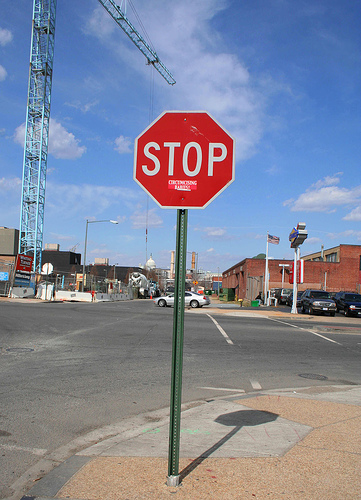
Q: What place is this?
A: It is a street.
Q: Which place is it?
A: It is a street.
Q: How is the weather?
A: It is clear.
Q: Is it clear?
A: Yes, it is clear.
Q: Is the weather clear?
A: Yes, it is clear.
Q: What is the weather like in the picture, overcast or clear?
A: It is clear.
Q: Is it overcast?
A: No, it is clear.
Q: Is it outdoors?
A: Yes, it is outdoors.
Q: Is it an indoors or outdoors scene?
A: It is outdoors.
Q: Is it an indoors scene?
A: No, it is outdoors.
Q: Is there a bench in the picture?
A: No, there are no benches.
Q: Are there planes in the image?
A: No, there are no planes.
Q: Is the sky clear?
A: Yes, the sky is clear.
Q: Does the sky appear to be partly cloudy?
A: No, the sky is clear.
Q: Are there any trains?
A: No, there are no trains.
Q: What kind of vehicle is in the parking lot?
A: The vehicles are cars.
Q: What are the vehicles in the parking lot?
A: The vehicles are cars.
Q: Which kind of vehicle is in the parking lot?
A: The vehicles are cars.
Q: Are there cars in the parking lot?
A: Yes, there are cars in the parking lot.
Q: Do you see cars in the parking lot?
A: Yes, there are cars in the parking lot.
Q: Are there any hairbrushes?
A: No, there are no hairbrushes.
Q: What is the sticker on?
A: The sticker is on the sign.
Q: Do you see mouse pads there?
A: No, there are no mouse pads.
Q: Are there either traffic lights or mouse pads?
A: No, there are no mouse pads or traffic lights.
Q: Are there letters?
A: Yes, there are letters.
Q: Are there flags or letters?
A: Yes, there are letters.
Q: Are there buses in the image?
A: No, there are no buses.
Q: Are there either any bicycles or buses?
A: No, there are no buses or bicycles.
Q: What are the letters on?
A: The letters are on the sign.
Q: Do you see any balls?
A: No, there are no balls.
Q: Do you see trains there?
A: No, there are no trains.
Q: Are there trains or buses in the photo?
A: No, there are no trains or buses.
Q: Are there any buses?
A: No, there are no buses.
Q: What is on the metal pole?
A: The sign is on the pole.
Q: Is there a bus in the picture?
A: No, there are no buses.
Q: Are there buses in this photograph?
A: No, there are no buses.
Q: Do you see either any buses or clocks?
A: No, there are no buses or clocks.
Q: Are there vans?
A: No, there are no vans.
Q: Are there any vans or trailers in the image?
A: No, there are no vans or trailers.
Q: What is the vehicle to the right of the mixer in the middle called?
A: The vehicle is a car.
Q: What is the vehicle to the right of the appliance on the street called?
A: The vehicle is a car.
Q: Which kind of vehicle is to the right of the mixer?
A: The vehicle is a car.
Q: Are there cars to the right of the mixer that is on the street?
A: Yes, there is a car to the right of the mixer.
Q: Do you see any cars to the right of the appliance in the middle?
A: Yes, there is a car to the right of the mixer.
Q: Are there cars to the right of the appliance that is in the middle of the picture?
A: Yes, there is a car to the right of the mixer.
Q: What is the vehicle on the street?
A: The vehicle is a car.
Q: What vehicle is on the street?
A: The vehicle is a car.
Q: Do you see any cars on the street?
A: Yes, there is a car on the street.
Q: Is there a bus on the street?
A: No, there is a car on the street.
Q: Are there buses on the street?
A: No, there is a car on the street.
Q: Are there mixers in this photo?
A: Yes, there is a mixer.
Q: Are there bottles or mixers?
A: Yes, there is a mixer.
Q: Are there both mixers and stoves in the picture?
A: No, there is a mixer but no stoves.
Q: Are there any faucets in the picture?
A: No, there are no faucets.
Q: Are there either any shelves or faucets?
A: No, there are no faucets or shelves.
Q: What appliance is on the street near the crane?
A: The appliance is a mixer.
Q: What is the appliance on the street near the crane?
A: The appliance is a mixer.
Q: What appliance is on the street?
A: The appliance is a mixer.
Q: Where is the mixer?
A: The mixer is on the street.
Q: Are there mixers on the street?
A: Yes, there is a mixer on the street.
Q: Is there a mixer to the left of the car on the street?
A: Yes, there is a mixer to the left of the car.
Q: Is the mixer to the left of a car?
A: Yes, the mixer is to the left of a car.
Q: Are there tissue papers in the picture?
A: No, there are no tissue papers.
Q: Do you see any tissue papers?
A: No, there are no tissue papers.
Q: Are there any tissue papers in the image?
A: No, there are no tissue papers.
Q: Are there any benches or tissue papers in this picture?
A: No, there are no tissue papers or benches.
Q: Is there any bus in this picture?
A: No, there are no buses.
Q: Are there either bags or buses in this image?
A: No, there are no buses or bags.